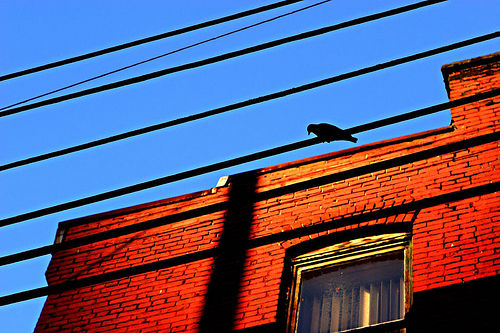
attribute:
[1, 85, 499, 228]
wire — black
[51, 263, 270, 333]
bricks — red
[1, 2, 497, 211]
sky — blue